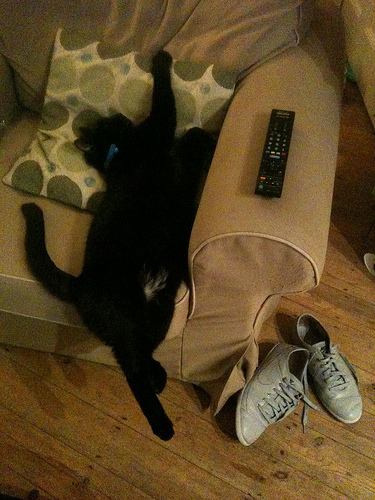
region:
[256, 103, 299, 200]
black remote on tan couch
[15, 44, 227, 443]
black cat stretched out on tan chair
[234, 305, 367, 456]
pair of white tennis shoes with loose laces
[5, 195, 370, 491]
brown wooden oak floor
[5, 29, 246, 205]
green and white polka dot pillow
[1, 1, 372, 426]
large over stuffed tan chair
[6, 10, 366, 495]
indoor living room scene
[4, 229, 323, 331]
piping lining tan upholstery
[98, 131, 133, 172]
blue collar on black cat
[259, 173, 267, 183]
orange button on black remote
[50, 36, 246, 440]
black cat stretched out on couch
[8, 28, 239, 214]
white throw pillow with green polka dots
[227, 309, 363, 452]
white sneakers on side of couch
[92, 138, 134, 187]
blue collar on cat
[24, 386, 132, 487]
wooden floor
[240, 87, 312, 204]
black remote control on couch arm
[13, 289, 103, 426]
shadow cast by cat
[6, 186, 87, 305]
black tail of cat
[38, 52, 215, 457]
cat sleeping in odd position on couch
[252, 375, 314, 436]
white shoelaces of sneakers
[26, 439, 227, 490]
the tiles are made of wood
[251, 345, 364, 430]
the shoes are grey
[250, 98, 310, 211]
the remote is black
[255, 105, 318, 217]
the remote is on the soffa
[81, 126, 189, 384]
the cat is black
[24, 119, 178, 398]
the cat is sleeping on the pillow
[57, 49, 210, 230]
the cat has a blue colar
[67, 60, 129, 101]
there are green circles on the pillow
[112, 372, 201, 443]
the feets are not touching the ground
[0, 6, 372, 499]
the scene is indoors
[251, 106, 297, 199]
black television remote control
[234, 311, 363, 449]
pair of gray shoes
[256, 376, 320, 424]
shoes with gray strings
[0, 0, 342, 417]
a brown velvet sofa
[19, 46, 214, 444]
a long black cat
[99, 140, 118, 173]
a blue cat collar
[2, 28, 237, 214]
a green, blue and whit pillow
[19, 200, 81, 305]
a long black tail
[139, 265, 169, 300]
white hair on stomach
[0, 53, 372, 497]
brown and yellow wooden floor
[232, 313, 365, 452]
Tennis shoes on floor.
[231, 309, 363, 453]
Tennis shoes are gray.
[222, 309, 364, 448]
Tennis shoes beside chair.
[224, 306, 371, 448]
Tennis shoes on hardwood floor.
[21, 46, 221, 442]
Cat is laying in chair.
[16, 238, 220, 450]
Cat's hind legs hanging over edge of chair.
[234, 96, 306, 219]
Remote control on arm of chair.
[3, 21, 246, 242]
Square pillow in chair.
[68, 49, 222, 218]
Cat's head and front paws on pillow.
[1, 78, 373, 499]
Floor is a light hardwood.